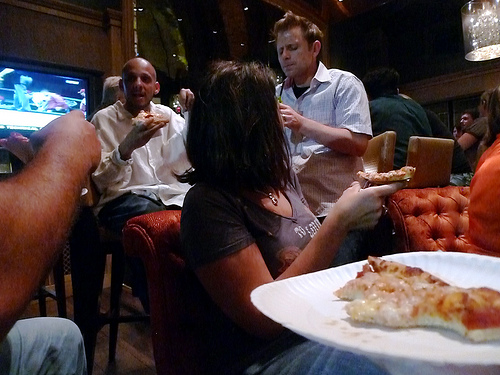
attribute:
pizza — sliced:
[336, 250, 498, 346]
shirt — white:
[88, 97, 195, 206]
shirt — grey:
[180, 186, 320, 266]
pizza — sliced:
[354, 157, 420, 186]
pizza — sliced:
[131, 106, 176, 128]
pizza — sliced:
[4, 127, 92, 191]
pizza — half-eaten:
[340, 254, 498, 342]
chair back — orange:
[386, 184, 496, 255]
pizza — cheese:
[349, 260, 499, 340]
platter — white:
[311, 254, 488, 346]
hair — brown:
[168, 71, 392, 373]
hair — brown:
[275, 10, 325, 45]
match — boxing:
[7, 74, 74, 117]